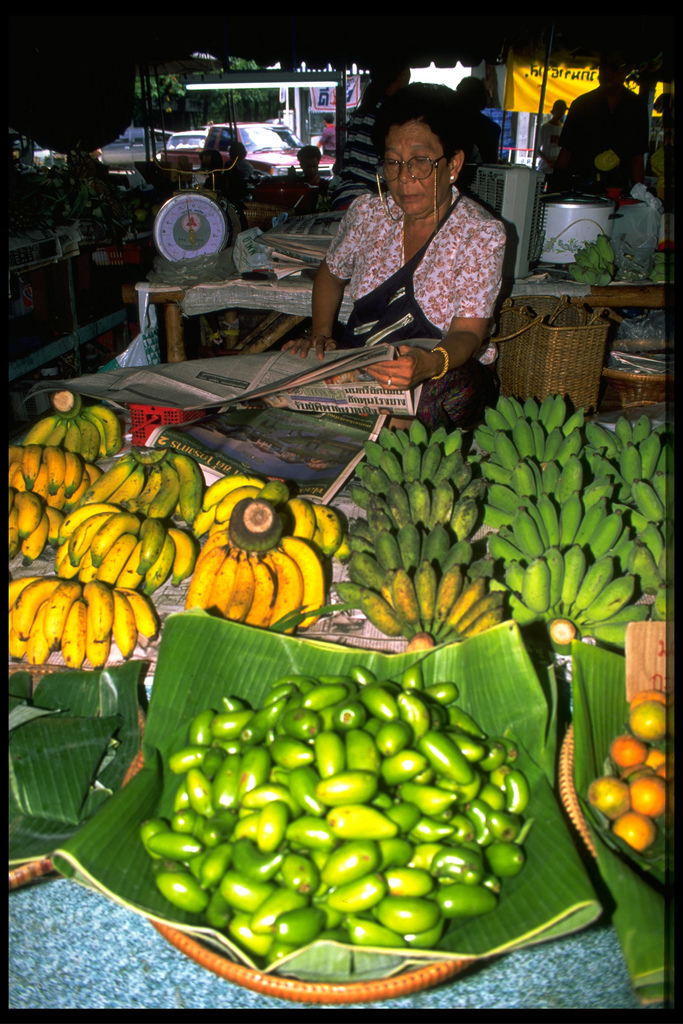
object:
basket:
[5, 663, 138, 868]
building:
[0, 3, 679, 1010]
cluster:
[6, 392, 329, 651]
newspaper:
[28, 339, 443, 422]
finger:
[360, 358, 405, 382]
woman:
[281, 42, 507, 453]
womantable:
[6, 392, 678, 1010]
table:
[9, 391, 680, 1009]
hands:
[272, 301, 476, 396]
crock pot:
[535, 184, 619, 263]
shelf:
[115, 262, 676, 396]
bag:
[96, 276, 162, 372]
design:
[141, 321, 161, 375]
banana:
[92, 514, 142, 566]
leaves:
[16, 666, 112, 813]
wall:
[76, 165, 160, 258]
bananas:
[122, 471, 231, 665]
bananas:
[483, 465, 615, 627]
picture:
[274, 417, 359, 466]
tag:
[218, 354, 312, 396]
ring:
[384, 363, 400, 398]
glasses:
[365, 131, 456, 187]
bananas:
[199, 463, 566, 638]